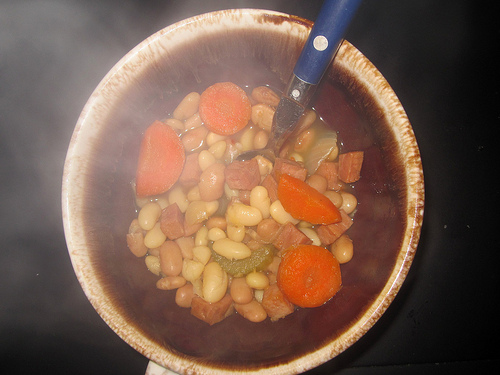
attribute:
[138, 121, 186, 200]
carrot — orange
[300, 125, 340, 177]
paprika — a piece, cooked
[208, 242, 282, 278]
paprika — a piece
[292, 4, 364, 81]
handle — blue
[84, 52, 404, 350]
soup — dark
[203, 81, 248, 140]
carrot — a piece, cooked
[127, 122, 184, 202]
carrot — a piece, cooked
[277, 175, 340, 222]
carrot — a piece, cooked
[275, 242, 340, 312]
carrot — a piece, cooked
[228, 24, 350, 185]
spoon — steel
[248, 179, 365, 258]
carrot — orange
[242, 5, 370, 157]
handle — blue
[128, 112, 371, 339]
soup — red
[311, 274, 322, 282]
piece — cooked , a carot 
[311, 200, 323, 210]
piece — cooked , a carot 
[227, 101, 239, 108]
piece — cooked , a carot 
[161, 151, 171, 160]
piece — cooked , a carot 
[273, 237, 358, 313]
carrot — orange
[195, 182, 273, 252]
beans — yellow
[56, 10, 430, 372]
bowl — white